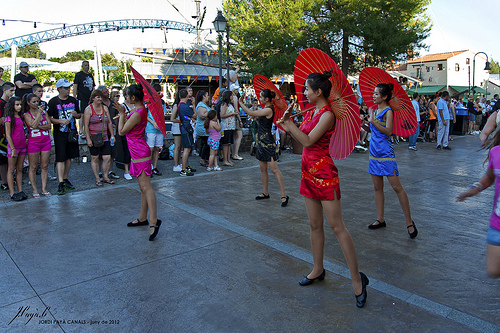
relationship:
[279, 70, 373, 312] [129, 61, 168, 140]
woman has umbrella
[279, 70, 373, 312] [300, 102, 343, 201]
woman has a dress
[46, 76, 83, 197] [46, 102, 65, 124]
man has arm